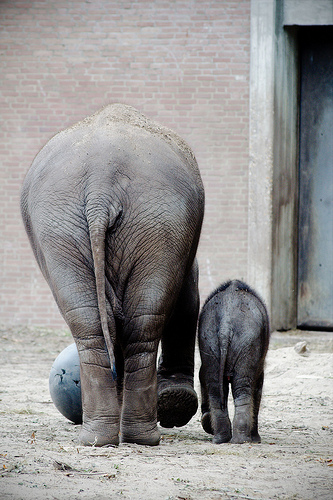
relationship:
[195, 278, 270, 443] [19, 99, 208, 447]
elephant walking with elephant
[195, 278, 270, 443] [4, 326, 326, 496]
elephant on ground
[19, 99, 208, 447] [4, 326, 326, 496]
elephant standing on ground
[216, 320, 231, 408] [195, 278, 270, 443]
tail on elephant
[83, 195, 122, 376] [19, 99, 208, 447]
tail on elephant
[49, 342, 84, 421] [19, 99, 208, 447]
ball in front elephant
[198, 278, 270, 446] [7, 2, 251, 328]
elephant in front of wall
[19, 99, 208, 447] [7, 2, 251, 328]
elephant in front of wall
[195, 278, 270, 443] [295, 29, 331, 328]
elephant in front of door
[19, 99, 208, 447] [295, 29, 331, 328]
elephant in front of door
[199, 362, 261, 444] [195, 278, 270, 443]
legs of elephant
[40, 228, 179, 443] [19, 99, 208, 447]
legs of elephant